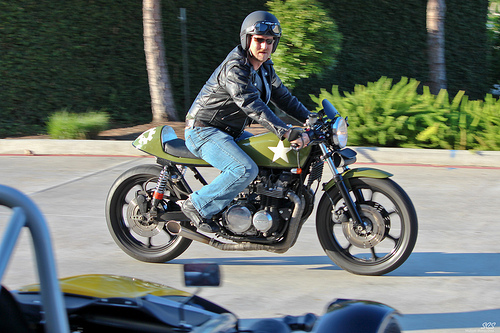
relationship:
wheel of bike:
[311, 168, 423, 281] [100, 96, 422, 279]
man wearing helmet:
[182, 9, 329, 228] [221, 5, 303, 69]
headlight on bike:
[330, 114, 350, 147] [100, 96, 422, 279]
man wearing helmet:
[182, 9, 329, 228] [236, 9, 282, 57]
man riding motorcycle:
[182, 9, 329, 228] [106, 98, 418, 275]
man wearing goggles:
[185, 11, 328, 229] [251, 36, 276, 45]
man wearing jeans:
[182, 9, 329, 228] [180, 126, 256, 216]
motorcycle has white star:
[106, 98, 418, 275] [266, 140, 299, 166]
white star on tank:
[266, 140, 299, 166] [241, 125, 311, 167]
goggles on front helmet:
[248, 36, 276, 45] [235, 11, 285, 53]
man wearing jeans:
[182, 9, 329, 228] [189, 120, 251, 219]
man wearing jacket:
[182, 9, 329, 228] [184, 46, 314, 137]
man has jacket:
[182, 9, 329, 228] [181, 62, 303, 124]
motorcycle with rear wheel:
[106, 98, 418, 275] [103, 164, 199, 265]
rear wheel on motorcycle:
[90, 167, 199, 262] [106, 98, 417, 276]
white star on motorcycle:
[269, 140, 299, 166] [106, 98, 417, 276]